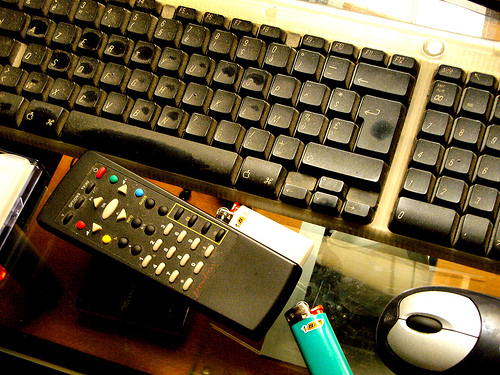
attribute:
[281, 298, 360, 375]
lighter — blue, disposable, light green, teal, aqua blue, bic, green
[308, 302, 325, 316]
button — red, light gray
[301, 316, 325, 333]
logo — yellow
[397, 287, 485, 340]
button — light gray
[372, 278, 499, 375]
mouse — black, gray, wireless, silver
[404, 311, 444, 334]
wheel — black, scroll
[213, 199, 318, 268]
lighter — white, disposable, small, bic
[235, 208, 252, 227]
logo — orange, yellow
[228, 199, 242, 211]
button — red, plastic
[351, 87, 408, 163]
key — black, enter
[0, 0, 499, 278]
keyboard — worn, used, black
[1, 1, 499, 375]
desk — glass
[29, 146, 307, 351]
remote — television, tv, black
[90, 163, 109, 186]
button — power, red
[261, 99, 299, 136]
key — m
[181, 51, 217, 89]
key — u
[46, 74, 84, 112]
key — x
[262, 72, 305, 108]
key — p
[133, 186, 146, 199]
button — blue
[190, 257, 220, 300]
print — red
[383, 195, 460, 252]
button — circle